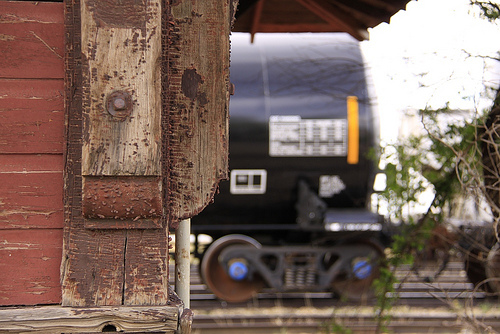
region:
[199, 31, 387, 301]
a black tanker car on a train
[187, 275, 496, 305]
railroad track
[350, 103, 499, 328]
a green branch from a bush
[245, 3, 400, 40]
rafters from the roof of the train station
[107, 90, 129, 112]
a rusty bolt in the wall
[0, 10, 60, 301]
red wood on side of building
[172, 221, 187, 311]
old white pipe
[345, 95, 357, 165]
yellow line on taker car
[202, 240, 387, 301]
train wheels on tanker car of train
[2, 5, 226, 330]
corner of the train station on the left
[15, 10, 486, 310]
train passing a wooden building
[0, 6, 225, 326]
weathered wood pieces on a building corner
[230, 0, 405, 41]
black overhang with red supports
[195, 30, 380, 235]
large black cylinder over wheels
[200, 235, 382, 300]
rusty metal wheels with blue centers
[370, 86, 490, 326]
vines with and without leaves hanging down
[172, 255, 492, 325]
straight rows of railroad tracks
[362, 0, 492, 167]
bright light in front of engine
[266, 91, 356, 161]
white and black panel next to orange stripe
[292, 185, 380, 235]
square platform next to curved support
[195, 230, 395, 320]
wheels of a locomotive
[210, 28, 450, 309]
a locomotive on rails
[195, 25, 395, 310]
locomotive has a yellow stripe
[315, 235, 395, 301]
center of wheel is blue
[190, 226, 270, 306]
center of wheel is blue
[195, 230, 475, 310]
rails under a locomotive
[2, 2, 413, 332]
a locomotive behind a building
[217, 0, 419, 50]
the roof of a building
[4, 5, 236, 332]
wall of building is made of wood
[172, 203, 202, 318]
a gray pipe on wall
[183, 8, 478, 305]
train on tracks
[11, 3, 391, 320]
a wooden train cart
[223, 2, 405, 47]
the underhang of the structure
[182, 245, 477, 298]
four train track rails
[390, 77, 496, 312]
shrubs and weeds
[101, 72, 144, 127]
a rusted bolt on the wood panel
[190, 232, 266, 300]
metal wheel with a blue center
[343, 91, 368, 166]
yellow sticker on the train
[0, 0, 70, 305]
wood with old red paint on it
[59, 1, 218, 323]
wood looks really old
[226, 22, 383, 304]
back end of black train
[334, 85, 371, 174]
yellow line on back of train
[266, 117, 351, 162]
black and white sign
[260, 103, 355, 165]
sign on back of train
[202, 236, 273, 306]
small rusted wheel of train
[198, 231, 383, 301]
bottom wheels of train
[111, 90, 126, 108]
small metal screw in wood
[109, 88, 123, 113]
small metal washer on screw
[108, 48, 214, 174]
brown wood peeling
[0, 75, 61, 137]
wooden boards painted red